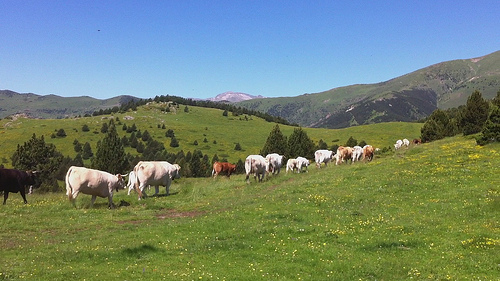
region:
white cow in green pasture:
[63, 163, 125, 209]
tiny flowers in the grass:
[272, 239, 304, 261]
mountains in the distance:
[2, 83, 491, 119]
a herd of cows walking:
[2, 135, 399, 200]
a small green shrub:
[459, 93, 490, 138]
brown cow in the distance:
[212, 158, 235, 179]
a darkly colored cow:
[1, 167, 43, 202]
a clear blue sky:
[109, 14, 316, 65]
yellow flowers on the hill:
[445, 137, 477, 164]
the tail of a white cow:
[132, 164, 139, 186]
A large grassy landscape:
[0, 53, 499, 278]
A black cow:
[0, 165, 43, 206]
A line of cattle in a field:
[0, 138, 419, 214]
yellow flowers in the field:
[0, 136, 484, 279]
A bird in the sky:
[95, 26, 104, 36]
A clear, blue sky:
[0, 0, 497, 97]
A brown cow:
[206, 156, 237, 177]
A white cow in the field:
[242, 152, 267, 182]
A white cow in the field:
[263, 147, 284, 174]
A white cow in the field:
[313, 145, 333, 165]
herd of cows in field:
[1, 122, 498, 210]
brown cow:
[203, 155, 239, 190]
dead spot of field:
[116, 206, 202, 226]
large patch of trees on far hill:
[299, 86, 439, 128]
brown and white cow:
[331, 141, 352, 163]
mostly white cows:
[5, 130, 460, 198]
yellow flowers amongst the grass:
[2, 141, 498, 273]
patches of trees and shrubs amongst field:
[31, 110, 211, 184]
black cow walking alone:
[6, 163, 45, 206]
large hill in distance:
[194, 82, 281, 111]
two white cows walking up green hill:
[68, 157, 182, 209]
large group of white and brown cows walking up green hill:
[241, 139, 377, 181]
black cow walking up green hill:
[1, 163, 41, 207]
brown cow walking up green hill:
[211, 158, 237, 181]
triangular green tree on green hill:
[93, 123, 129, 173]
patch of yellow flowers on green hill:
[443, 142, 498, 163]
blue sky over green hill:
[3, 3, 498, 71]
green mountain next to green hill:
[239, 48, 496, 120]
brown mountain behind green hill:
[202, 89, 254, 103]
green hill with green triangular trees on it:
[3, 96, 409, 153]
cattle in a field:
[5, 136, 410, 230]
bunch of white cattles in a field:
[55, 141, 425, 211]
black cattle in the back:
[1, 162, 42, 207]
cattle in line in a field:
[0, 126, 417, 236]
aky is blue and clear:
[0, 0, 491, 111]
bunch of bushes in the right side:
[417, 92, 498, 143]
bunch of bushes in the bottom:
[0, 119, 298, 177]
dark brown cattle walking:
[210, 162, 245, 179]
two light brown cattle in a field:
[337, 142, 387, 174]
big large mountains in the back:
[4, 52, 498, 166]